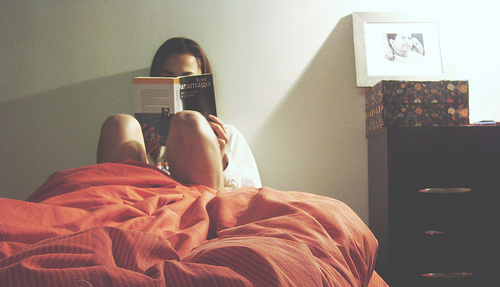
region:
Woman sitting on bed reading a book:
[86, 35, 266, 188]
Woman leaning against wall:
[85, 34, 269, 186]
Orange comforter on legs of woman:
[0, 152, 395, 285]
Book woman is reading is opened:
[130, 71, 217, 145]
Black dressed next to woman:
[362, 126, 498, 284]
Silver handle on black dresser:
[417, 184, 474, 195]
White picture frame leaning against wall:
[350, 8, 455, 80]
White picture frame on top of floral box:
[351, 9, 446, 86]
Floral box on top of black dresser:
[362, 79, 468, 129]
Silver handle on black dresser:
[414, 267, 477, 279]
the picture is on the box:
[350, 3, 463, 79]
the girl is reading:
[78, 26, 270, 185]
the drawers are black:
[375, 127, 490, 266]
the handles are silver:
[417, 180, 468, 200]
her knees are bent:
[87, 106, 212, 141]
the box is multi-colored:
[372, 76, 474, 130]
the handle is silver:
[415, 176, 483, 201]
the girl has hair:
[165, 35, 192, 52]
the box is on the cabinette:
[376, 77, 483, 137]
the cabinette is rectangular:
[360, 119, 498, 267]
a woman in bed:
[4, 13, 374, 283]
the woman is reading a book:
[88, 28, 262, 195]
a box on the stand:
[360, 78, 499, 284]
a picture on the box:
[348, 6, 476, 124]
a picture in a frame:
[348, 6, 453, 87]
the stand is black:
[363, 118, 499, 284]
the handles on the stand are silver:
[418, 178, 477, 281]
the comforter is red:
[1, 161, 378, 285]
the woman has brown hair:
[148, 35, 211, 79]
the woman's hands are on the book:
[127, 68, 229, 159]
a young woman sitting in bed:
[84, 21, 267, 195]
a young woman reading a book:
[94, 13, 299, 265]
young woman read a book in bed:
[57, 0, 300, 241]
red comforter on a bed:
[16, 183, 376, 280]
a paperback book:
[129, 68, 227, 147]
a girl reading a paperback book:
[71, 33, 268, 191]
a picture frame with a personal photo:
[335, 6, 469, 88]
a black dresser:
[363, 119, 493, 284]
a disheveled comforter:
[28, 164, 401, 279]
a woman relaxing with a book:
[81, 33, 287, 214]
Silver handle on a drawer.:
[415, 181, 477, 195]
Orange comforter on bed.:
[1, 158, 399, 285]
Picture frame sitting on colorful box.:
[350, 12, 456, 88]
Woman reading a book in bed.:
[92, 31, 243, 196]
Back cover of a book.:
[130, 73, 180, 150]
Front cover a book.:
[175, 73, 219, 128]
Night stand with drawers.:
[366, 125, 498, 285]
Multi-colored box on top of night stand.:
[362, 78, 472, 132]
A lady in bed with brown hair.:
[142, 31, 232, 186]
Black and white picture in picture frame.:
[386, 33, 430, 65]